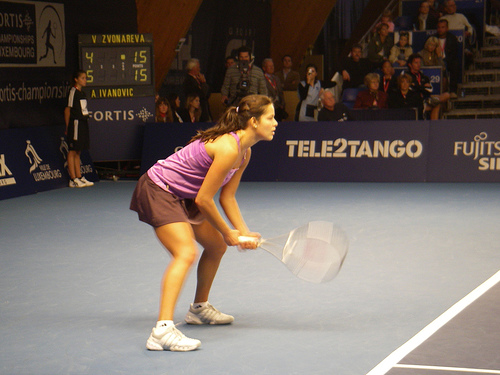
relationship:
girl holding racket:
[130, 93, 277, 352] [246, 202, 353, 294]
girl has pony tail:
[130, 93, 277, 352] [190, 102, 242, 140]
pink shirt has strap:
[147, 129, 248, 198] [228, 126, 245, 156]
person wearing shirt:
[387, 74, 424, 118] [391, 87, 421, 114]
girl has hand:
[130, 93, 277, 352] [225, 229, 256, 251]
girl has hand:
[130, 93, 277, 352] [234, 225, 266, 248]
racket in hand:
[235, 218, 351, 287] [225, 229, 256, 251]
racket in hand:
[235, 218, 351, 287] [234, 225, 266, 248]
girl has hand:
[130, 93, 277, 352] [225, 227, 245, 250]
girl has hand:
[130, 93, 277, 352] [237, 227, 261, 246]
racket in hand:
[235, 218, 351, 287] [225, 227, 245, 250]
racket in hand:
[235, 218, 351, 287] [237, 227, 261, 246]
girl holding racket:
[130, 93, 277, 352] [50, 18, 59, 41]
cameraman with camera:
[219, 47, 272, 108] [237, 58, 253, 70]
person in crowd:
[313, 89, 350, 121] [150, 6, 477, 118]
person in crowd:
[355, 72, 387, 116] [150, 6, 477, 118]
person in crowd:
[387, 76, 424, 118] [150, 6, 477, 118]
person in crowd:
[181, 93, 205, 123] [150, 6, 477, 118]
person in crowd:
[404, 53, 429, 93] [150, 6, 477, 118]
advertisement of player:
[29, 1, 63, 76] [37, 14, 63, 66]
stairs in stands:
[446, 17, 498, 139] [330, 4, 492, 118]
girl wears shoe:
[116, 91, 296, 373] [142, 318, 204, 359]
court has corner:
[6, 169, 498, 373] [359, 357, 402, 374]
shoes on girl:
[132, 295, 245, 357] [130, 93, 277, 352]